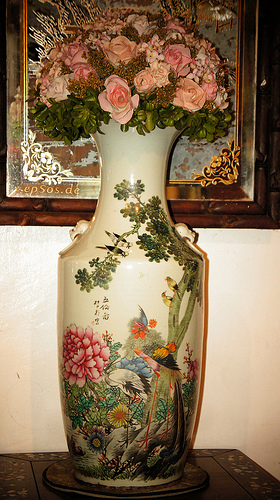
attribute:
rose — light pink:
[96, 72, 139, 125]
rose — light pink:
[170, 76, 206, 115]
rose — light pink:
[101, 34, 137, 67]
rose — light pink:
[133, 68, 157, 93]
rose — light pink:
[143, 58, 171, 86]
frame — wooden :
[6, 0, 264, 218]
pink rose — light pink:
[172, 78, 207, 111]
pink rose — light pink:
[97, 74, 139, 123]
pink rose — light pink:
[98, 36, 136, 65]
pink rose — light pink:
[59, 41, 86, 62]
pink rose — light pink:
[36, 70, 72, 101]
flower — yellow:
[106, 403, 132, 426]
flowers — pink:
[42, 9, 234, 141]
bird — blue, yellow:
[142, 264, 186, 316]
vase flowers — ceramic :
[44, 10, 234, 438]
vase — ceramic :
[30, 129, 231, 491]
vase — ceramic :
[57, 114, 206, 488]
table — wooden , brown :
[2, 448, 278, 498]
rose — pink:
[168, 69, 203, 111]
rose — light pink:
[162, 42, 192, 78]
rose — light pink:
[46, 73, 75, 103]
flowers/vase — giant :
[28, 15, 230, 498]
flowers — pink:
[203, 57, 227, 104]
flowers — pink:
[85, 49, 181, 137]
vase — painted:
[62, 140, 218, 480]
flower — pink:
[92, 73, 148, 126]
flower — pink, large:
[59, 319, 109, 387]